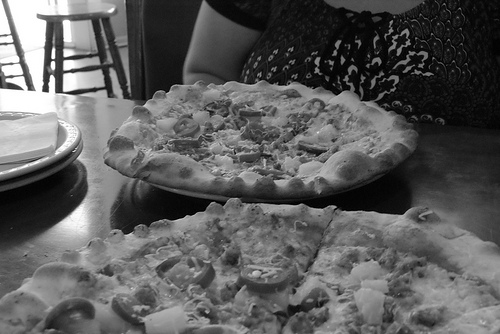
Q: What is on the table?
A: Pizzas.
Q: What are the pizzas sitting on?
A: A table.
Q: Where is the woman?
A: By the table.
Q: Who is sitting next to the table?
A: A woman.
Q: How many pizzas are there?
A: Two.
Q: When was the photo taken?
A: During the day.